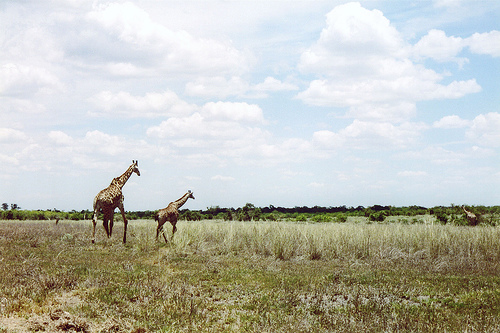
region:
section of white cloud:
[355, 28, 369, 62]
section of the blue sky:
[453, 22, 461, 29]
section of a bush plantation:
[400, 207, 425, 209]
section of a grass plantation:
[341, 224, 381, 241]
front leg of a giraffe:
[123, 215, 125, 245]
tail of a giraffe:
[92, 202, 97, 222]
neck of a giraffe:
[175, 198, 185, 204]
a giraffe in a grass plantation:
[105, 170, 129, 229]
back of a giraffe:
[102, 190, 114, 198]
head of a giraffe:
[133, 164, 140, 174]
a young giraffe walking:
[136, 177, 209, 257]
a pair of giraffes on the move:
[71, 156, 224, 254]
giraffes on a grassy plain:
[70, 148, 337, 258]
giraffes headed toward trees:
[77, 144, 247, 254]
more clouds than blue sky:
[3, 6, 497, 256]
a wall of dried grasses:
[187, 216, 497, 266]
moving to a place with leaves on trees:
[69, 148, 279, 255]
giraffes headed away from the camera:
[75, 144, 233, 263]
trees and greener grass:
[209, 205, 498, 227]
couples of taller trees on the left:
[0, 187, 42, 225]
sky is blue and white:
[60, 12, 443, 223]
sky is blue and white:
[26, 30, 417, 200]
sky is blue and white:
[73, 68, 475, 173]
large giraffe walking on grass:
[89, 157, 143, 246]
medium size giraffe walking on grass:
[150, 187, 194, 247]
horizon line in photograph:
[1, 217, 496, 224]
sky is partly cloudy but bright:
[1, 2, 496, 203]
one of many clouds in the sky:
[290, 3, 420, 70]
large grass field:
[0, 220, 497, 330]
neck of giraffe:
[115, 166, 132, 194]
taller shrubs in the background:
[0, 208, 496, 215]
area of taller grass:
[182, 222, 495, 277]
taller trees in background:
[1, 199, 20, 216]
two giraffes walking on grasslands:
[66, 155, 317, 251]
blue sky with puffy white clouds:
[30, 21, 467, 193]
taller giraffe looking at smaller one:
[75, 152, 200, 252]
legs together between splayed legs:
[75, 155, 140, 255]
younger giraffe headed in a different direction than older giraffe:
[86, 150, 206, 255]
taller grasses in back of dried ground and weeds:
[175, 215, 475, 310]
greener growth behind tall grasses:
[215, 185, 490, 235]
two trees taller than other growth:
[0, 185, 30, 227]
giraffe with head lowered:
[145, 150, 206, 252]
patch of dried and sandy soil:
[11, 295, 106, 330]